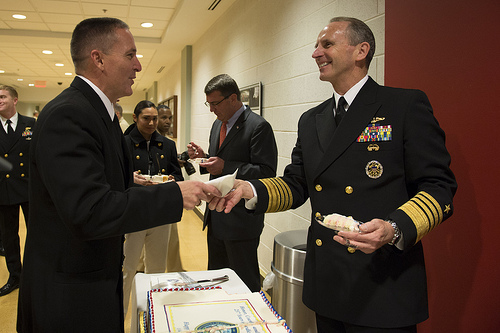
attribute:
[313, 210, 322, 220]
button — small, gold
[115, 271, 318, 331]
cake — big, for celebration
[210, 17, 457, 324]
man — holding plate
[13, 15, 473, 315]
men — smiling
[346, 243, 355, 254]
button — small, gold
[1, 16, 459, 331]
men — talking, wearing uniform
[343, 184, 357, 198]
button — gold, small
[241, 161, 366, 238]
stripes — gold, rank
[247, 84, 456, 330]
jacket — small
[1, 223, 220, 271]
floor — tan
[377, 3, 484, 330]
wall — red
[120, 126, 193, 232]
jacket — black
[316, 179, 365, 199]
button — gold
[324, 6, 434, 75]
hair — short